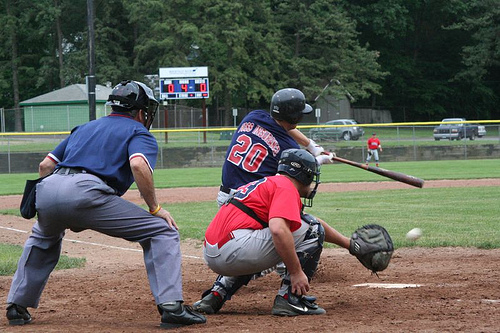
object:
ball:
[405, 227, 423, 241]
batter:
[217, 88, 336, 209]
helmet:
[270, 88, 314, 125]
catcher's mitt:
[350, 223, 395, 279]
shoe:
[270, 293, 326, 317]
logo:
[287, 303, 309, 312]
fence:
[316, 120, 500, 164]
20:
[227, 133, 269, 173]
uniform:
[221, 109, 301, 191]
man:
[366, 133, 383, 167]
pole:
[315, 108, 322, 125]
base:
[352, 282, 421, 288]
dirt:
[1, 179, 500, 333]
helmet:
[278, 148, 321, 199]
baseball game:
[2, 0, 499, 331]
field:
[0, 162, 499, 333]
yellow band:
[0, 118, 500, 135]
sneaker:
[158, 306, 208, 329]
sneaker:
[5, 301, 34, 326]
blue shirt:
[221, 110, 301, 190]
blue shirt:
[45, 113, 159, 197]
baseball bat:
[320, 151, 425, 189]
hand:
[318, 152, 337, 164]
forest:
[0, 6, 499, 118]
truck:
[433, 118, 479, 142]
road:
[0, 135, 500, 142]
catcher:
[193, 147, 394, 318]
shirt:
[204, 175, 302, 250]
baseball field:
[13, 158, 500, 325]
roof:
[17, 83, 113, 105]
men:
[6, 81, 207, 333]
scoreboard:
[158, 66, 210, 100]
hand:
[349, 233, 383, 257]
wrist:
[148, 202, 161, 214]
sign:
[315, 108, 321, 117]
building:
[18, 82, 116, 131]